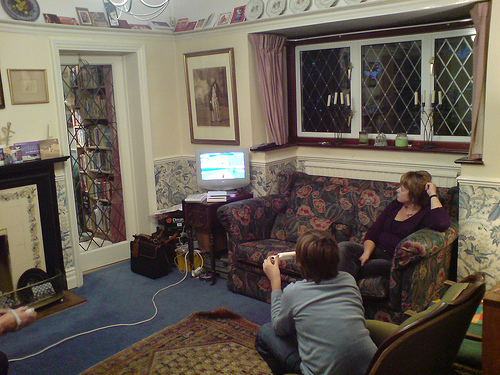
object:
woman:
[338, 171, 452, 284]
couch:
[215, 169, 460, 327]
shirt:
[364, 197, 453, 261]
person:
[252, 230, 384, 374]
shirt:
[270, 275, 386, 374]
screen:
[201, 153, 244, 179]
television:
[195, 150, 250, 190]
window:
[288, 29, 480, 147]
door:
[47, 36, 161, 271]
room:
[1, 0, 500, 374]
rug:
[77, 306, 271, 374]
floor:
[4, 259, 268, 374]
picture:
[182, 49, 240, 145]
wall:
[1, 22, 252, 268]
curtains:
[248, 32, 292, 144]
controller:
[269, 252, 297, 261]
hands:
[262, 255, 281, 283]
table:
[179, 194, 247, 285]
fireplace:
[0, 151, 73, 304]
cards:
[39, 137, 60, 161]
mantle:
[0, 154, 71, 174]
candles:
[326, 94, 332, 108]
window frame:
[291, 128, 474, 155]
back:
[363, 272, 490, 374]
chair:
[340, 268, 484, 374]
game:
[197, 153, 245, 180]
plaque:
[7, 67, 49, 105]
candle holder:
[326, 104, 351, 144]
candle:
[358, 128, 371, 146]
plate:
[0, 0, 41, 23]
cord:
[9, 246, 203, 369]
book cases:
[63, 63, 127, 242]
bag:
[129, 233, 172, 278]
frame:
[184, 45, 239, 146]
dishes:
[243, 0, 381, 19]